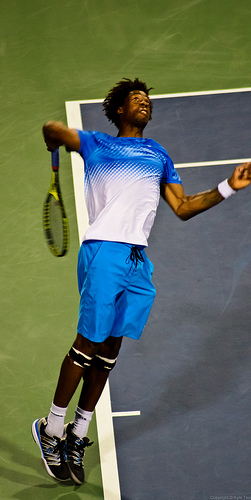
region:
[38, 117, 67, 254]
Tennis racket in players right hand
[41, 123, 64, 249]
Tennis racket in middle of swing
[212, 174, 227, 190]
White sweatband on player's wrist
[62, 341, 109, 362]
Knee supports on tennis player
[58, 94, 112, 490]
White court base line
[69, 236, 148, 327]
Blue shorts on tennis player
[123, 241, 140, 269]
Black draw string on players shorts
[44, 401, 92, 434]
White socks on tennis player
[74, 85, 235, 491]
Gray play area of tennis court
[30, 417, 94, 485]
Shoes on tennis player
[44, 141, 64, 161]
hes holding the racket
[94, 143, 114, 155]
his shirt is blue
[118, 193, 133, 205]
his shirt is white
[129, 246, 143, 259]
the cord is black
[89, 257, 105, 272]
the shorts are blue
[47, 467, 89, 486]
standing on tippy toes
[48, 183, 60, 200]
the racket is yellow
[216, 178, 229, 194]
the wrist band is white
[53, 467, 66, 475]
the shoes are black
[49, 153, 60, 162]
the handle is blue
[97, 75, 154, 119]
curly black hair of man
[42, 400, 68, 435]
medium length white sock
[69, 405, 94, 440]
medium length white sock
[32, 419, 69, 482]
blue and black tennis shoes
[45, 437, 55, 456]
silver on side of shoes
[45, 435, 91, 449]
black shoe laces of shoes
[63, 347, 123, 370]
white and black knee bands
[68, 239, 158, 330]
blue athletic shorts on man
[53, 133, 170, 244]
blue and white shirt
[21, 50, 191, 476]
he is looking to hit the ball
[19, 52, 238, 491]
this man is an athlete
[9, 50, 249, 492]
this man is a tennis player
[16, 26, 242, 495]
he is competing in a tennis match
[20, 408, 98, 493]
his tennis shoes are black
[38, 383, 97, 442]
his socks are white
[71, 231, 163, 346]
his shorts are blue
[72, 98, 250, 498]
the court is blue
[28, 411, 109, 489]
his shoes are black, silver, and blue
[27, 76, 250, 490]
A man playing tennis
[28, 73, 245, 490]
A man playing tennis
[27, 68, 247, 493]
A man playing tennis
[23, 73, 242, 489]
A man playing tennis